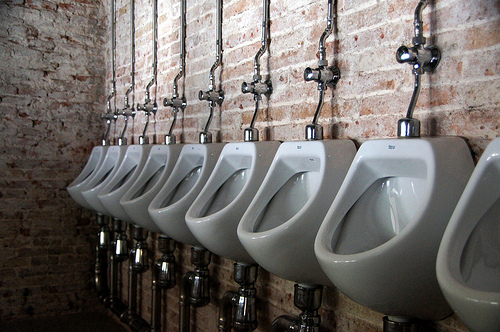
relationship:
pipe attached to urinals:
[394, 4, 433, 139] [65, 135, 493, 329]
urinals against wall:
[65, 135, 493, 329] [102, 7, 497, 141]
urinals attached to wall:
[65, 135, 493, 329] [102, 7, 497, 141]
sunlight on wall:
[135, 4, 174, 114] [102, 7, 497, 141]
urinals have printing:
[65, 135, 493, 329] [294, 142, 408, 151]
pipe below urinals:
[89, 214, 114, 321] [65, 135, 493, 329]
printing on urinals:
[294, 142, 408, 151] [65, 135, 493, 329]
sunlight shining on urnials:
[268, 134, 458, 211] [278, 137, 445, 272]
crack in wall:
[24, 57, 72, 90] [3, 8, 96, 331]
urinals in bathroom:
[65, 135, 493, 329] [4, 5, 497, 327]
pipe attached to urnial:
[394, 4, 433, 139] [394, 111, 430, 143]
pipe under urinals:
[89, 214, 114, 321] [65, 135, 493, 329]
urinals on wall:
[65, 135, 493, 329] [102, 7, 497, 141]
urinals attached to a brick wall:
[65, 135, 493, 329] [102, 7, 497, 141]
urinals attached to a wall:
[65, 135, 493, 329] [102, 7, 497, 141]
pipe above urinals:
[394, 4, 433, 139] [65, 135, 493, 329]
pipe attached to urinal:
[394, 4, 433, 139] [315, 132, 479, 321]